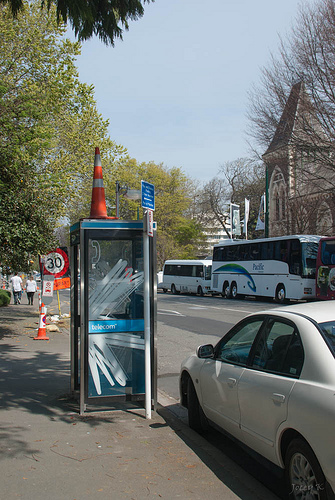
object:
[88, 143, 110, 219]
cone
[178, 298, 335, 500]
car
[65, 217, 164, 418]
telephone booth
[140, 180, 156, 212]
sign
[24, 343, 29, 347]
leaves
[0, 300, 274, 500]
pavement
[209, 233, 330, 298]
buses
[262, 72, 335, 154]
steeple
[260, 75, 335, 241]
building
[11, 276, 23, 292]
shirt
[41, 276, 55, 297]
signs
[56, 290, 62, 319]
pole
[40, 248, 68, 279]
speed limit sign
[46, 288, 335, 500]
road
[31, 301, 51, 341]
cone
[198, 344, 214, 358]
mirror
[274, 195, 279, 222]
windows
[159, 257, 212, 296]
bus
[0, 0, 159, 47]
tree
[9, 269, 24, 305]
man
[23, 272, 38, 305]
woman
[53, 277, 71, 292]
traffic signs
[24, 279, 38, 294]
tee shirt